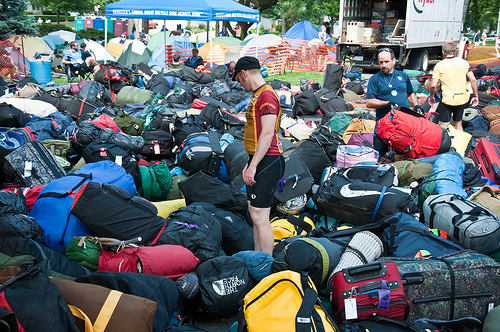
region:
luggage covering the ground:
[14, 45, 477, 315]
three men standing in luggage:
[228, 27, 475, 260]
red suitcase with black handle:
[330, 256, 401, 320]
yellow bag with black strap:
[240, 264, 320, 329]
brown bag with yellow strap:
[52, 271, 159, 330]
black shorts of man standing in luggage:
[245, 152, 285, 207]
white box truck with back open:
[337, 0, 464, 67]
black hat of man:
[223, 57, 263, 72]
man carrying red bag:
[363, 50, 448, 150]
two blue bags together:
[32, 159, 126, 247]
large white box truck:
[336, 0, 465, 72]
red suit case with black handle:
[332, 264, 409, 320]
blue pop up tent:
[105, 0, 260, 20]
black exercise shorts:
[247, 151, 284, 206]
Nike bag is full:
[320, 180, 411, 222]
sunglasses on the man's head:
[376, 47, 396, 73]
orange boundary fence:
[165, 43, 335, 75]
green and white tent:
[115, 41, 152, 68]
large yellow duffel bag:
[242, 270, 334, 328]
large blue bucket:
[31, 58, 52, 83]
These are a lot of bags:
[60, 131, 251, 329]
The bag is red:
[92, 235, 216, 295]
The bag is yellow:
[250, 294, 285, 319]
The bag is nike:
[348, 136, 398, 225]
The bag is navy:
[302, 169, 414, 227]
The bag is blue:
[25, 175, 72, 229]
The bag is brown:
[79, 292, 166, 327]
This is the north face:
[199, 251, 245, 329]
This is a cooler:
[22, 34, 58, 99]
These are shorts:
[240, 129, 301, 225]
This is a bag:
[66, 170, 178, 250]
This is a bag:
[329, 254, 426, 325]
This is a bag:
[379, 240, 495, 322]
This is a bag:
[91, 225, 206, 295]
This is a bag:
[186, 243, 257, 308]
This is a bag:
[230, 237, 278, 282]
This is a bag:
[279, 219, 351, 282]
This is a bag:
[171, 119, 251, 171]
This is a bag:
[283, 80, 320, 117]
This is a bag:
[314, 54, 352, 104]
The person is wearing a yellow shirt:
[429, 38, 479, 133]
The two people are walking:
[472, 28, 489, 48]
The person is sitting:
[61, 40, 100, 77]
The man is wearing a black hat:
[231, 53, 287, 260]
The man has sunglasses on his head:
[364, 45, 423, 158]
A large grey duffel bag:
[421, 190, 498, 252]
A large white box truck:
[338, 0, 471, 68]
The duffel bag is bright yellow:
[242, 265, 337, 330]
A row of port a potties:
[73, 14, 143, 38]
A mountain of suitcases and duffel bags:
[6, 75, 497, 328]